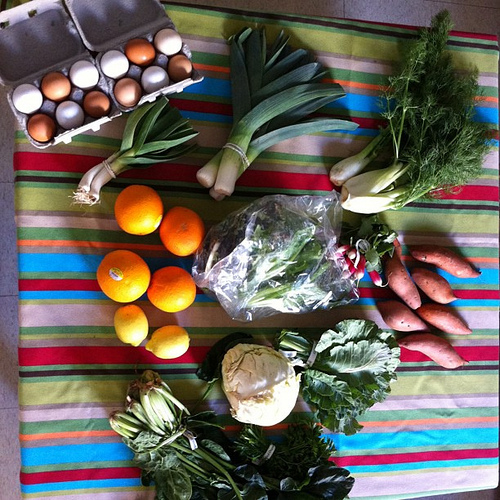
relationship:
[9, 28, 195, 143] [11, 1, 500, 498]
egges on top of table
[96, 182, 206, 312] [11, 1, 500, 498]
oranges on a table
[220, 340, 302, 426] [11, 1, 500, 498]
cabbage on a table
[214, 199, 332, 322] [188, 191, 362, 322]
vegetables in a bag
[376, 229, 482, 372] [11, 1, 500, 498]
sweet potatoes on a table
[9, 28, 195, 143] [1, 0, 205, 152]
eggs in a carton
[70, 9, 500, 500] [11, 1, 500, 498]
vegetables on a table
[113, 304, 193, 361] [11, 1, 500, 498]
lemons on a table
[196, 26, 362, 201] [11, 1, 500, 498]
fennel on a table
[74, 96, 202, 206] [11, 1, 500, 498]
leaks on a table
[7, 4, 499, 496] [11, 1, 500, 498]
fabric over table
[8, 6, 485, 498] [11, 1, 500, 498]
food on a table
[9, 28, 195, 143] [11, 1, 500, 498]
eggs on a table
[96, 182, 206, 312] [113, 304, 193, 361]
oranges next to lemons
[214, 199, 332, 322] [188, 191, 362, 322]
vegetables inside of bag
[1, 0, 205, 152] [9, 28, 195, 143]
carton with eggs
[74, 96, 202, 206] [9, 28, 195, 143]
leaks near eggs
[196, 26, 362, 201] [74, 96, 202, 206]
fennel near leaks